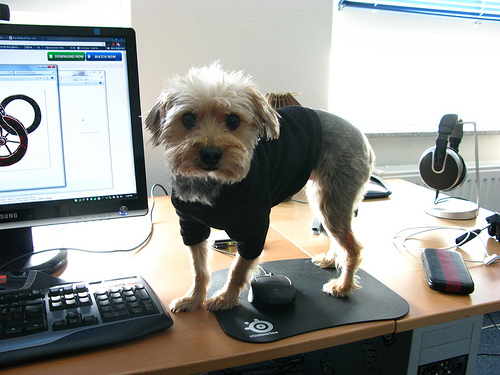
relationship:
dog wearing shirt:
[145, 64, 376, 314] [172, 107, 321, 259]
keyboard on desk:
[0, 272, 174, 364] [0, 177, 499, 374]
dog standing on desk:
[145, 64, 376, 314] [0, 177, 499, 374]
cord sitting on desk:
[394, 224, 499, 266] [0, 177, 499, 374]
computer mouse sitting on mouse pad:
[247, 272, 296, 314] [205, 257, 409, 343]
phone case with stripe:
[422, 247, 475, 295] [436, 248, 463, 292]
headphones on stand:
[421, 115, 467, 192] [428, 121, 480, 221]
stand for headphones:
[428, 121, 480, 221] [421, 115, 467, 192]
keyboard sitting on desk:
[0, 272, 174, 364] [0, 177, 499, 374]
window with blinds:
[326, 1, 499, 167] [339, 2, 499, 22]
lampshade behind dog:
[265, 92, 301, 108] [145, 64, 376, 314]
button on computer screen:
[47, 52, 86, 60] [0, 35, 137, 204]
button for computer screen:
[86, 52, 124, 62] [0, 35, 137, 204]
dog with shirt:
[145, 64, 376, 314] [172, 107, 321, 259]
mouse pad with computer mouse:
[205, 257, 409, 343] [247, 272, 296, 314]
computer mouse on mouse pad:
[247, 272, 296, 314] [205, 257, 409, 343]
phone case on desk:
[422, 247, 475, 295] [0, 177, 499, 374]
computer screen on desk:
[0, 35, 137, 204] [0, 177, 499, 374]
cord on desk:
[394, 224, 499, 266] [0, 177, 499, 374]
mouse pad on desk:
[205, 257, 409, 343] [0, 177, 499, 374]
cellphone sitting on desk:
[422, 247, 475, 293] [0, 177, 499, 374]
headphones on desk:
[421, 115, 467, 192] [0, 177, 499, 374]